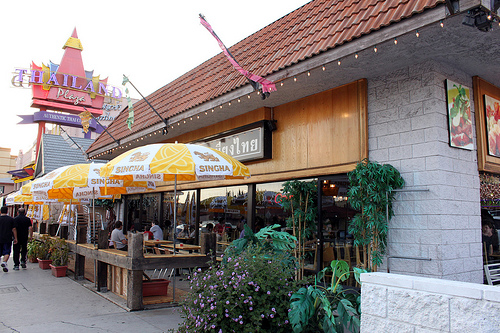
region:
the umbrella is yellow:
[84, 93, 248, 299]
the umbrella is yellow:
[71, 137, 348, 328]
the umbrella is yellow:
[79, 61, 320, 253]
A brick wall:
[412, 177, 472, 319]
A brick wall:
[375, 245, 429, 326]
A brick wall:
[397, 251, 435, 329]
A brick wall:
[397, 181, 432, 316]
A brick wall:
[395, 277, 417, 321]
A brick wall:
[391, 235, 416, 330]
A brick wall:
[372, 228, 404, 323]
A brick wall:
[394, 205, 456, 330]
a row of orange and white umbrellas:
[11, 135, 251, 224]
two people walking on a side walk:
[0, 202, 29, 252]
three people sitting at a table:
[105, 215, 164, 244]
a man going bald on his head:
[13, 202, 30, 222]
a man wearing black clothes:
[13, 200, 32, 268]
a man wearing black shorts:
[0, 200, 17, 259]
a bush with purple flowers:
[188, 258, 286, 317]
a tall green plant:
[341, 148, 395, 288]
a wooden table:
[158, 232, 208, 265]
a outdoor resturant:
[10, 158, 233, 283]